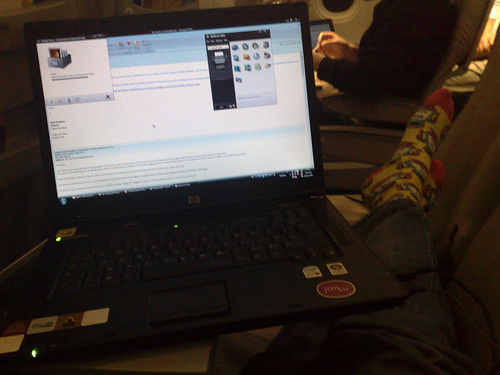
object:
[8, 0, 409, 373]
laptop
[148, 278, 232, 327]
mouse pad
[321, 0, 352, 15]
window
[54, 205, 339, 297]
keyboard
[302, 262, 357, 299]
sticker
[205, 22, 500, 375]
seat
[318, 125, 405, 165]
arm rest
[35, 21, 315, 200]
screen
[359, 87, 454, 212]
socks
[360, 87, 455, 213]
feet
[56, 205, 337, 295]
button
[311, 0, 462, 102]
person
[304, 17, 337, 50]
laptop